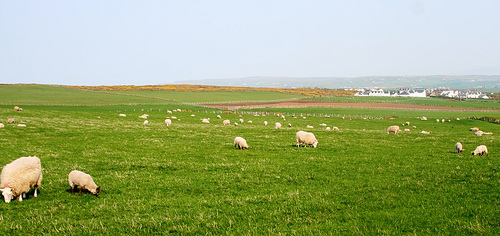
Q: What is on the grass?
A: The sheep.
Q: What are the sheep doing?
A: Eating grass.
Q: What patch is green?
A: The grass.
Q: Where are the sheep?
A: In a field.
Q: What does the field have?
A: Green grass.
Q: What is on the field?
A: Animals.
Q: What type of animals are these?
A: Sheep.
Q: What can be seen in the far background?
A: Mountains.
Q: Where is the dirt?
A: Behind the sheep.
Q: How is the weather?
A: Sunny.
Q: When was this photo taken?
A: In the daytime.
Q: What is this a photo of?
A: Sheep in a field.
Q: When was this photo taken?
A: During the day.